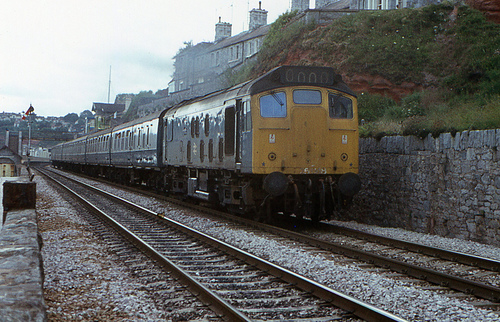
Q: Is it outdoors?
A: Yes, it is outdoors.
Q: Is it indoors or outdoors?
A: It is outdoors.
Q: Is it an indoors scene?
A: No, it is outdoors.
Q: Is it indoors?
A: No, it is outdoors.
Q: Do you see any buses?
A: No, there are no buses.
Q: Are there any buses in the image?
A: No, there are no buses.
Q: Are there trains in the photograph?
A: Yes, there is a train.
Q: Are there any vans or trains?
A: Yes, there is a train.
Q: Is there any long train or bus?
A: Yes, there is a long train.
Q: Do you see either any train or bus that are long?
A: Yes, the train is long.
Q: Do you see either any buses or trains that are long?
A: Yes, the train is long.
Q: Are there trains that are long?
A: Yes, there is a train that is long.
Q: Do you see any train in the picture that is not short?
A: Yes, there is a long train.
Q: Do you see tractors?
A: No, there are no tractors.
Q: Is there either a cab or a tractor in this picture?
A: No, there are no tractors or taxis.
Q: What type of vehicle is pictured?
A: The vehicle is a train.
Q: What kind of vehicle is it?
A: The vehicle is a train.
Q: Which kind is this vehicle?
A: That is a train.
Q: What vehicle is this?
A: That is a train.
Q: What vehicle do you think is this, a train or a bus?
A: That is a train.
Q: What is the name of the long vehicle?
A: The vehicle is a train.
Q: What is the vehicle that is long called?
A: The vehicle is a train.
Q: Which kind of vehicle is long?
A: The vehicle is a train.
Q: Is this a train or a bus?
A: This is a train.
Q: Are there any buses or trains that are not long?
A: No, there is a train but it is long.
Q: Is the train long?
A: Yes, the train is long.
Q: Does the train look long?
A: Yes, the train is long.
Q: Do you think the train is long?
A: Yes, the train is long.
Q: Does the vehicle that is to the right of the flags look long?
A: Yes, the train is long.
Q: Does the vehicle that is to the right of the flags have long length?
A: Yes, the train is long.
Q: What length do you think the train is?
A: The train is long.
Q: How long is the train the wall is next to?
A: The train is long.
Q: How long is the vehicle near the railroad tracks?
A: The train is long.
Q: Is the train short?
A: No, the train is long.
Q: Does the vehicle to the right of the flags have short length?
A: No, the train is long.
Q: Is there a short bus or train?
A: No, there is a train but it is long.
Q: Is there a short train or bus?
A: No, there is a train but it is long.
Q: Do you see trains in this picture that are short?
A: No, there is a train but it is long.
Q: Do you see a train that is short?
A: No, there is a train but it is long.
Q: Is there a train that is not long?
A: No, there is a train but it is long.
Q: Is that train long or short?
A: The train is long.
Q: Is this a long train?
A: Yes, this is a long train.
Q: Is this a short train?
A: No, this is a long train.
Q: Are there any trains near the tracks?
A: Yes, there is a train near the tracks.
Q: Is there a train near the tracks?
A: Yes, there is a train near the tracks.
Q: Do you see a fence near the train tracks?
A: No, there is a train near the train tracks.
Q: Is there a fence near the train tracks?
A: No, there is a train near the train tracks.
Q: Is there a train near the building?
A: Yes, there is a train near the building.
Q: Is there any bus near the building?
A: No, there is a train near the building.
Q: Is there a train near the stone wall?
A: Yes, there is a train near the wall.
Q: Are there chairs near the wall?
A: No, there is a train near the wall.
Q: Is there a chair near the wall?
A: No, there is a train near the wall.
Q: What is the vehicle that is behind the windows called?
A: The vehicle is a train.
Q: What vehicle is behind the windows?
A: The vehicle is a train.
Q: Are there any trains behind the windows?
A: Yes, there is a train behind the windows.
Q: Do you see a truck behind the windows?
A: No, there is a train behind the windows.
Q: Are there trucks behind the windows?
A: No, there is a train behind the windows.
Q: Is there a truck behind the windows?
A: No, there is a train behind the windows.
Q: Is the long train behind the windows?
A: Yes, the train is behind the windows.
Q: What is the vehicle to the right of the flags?
A: The vehicle is a train.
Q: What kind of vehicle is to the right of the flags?
A: The vehicle is a train.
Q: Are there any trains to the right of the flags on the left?
A: Yes, there is a train to the right of the flags.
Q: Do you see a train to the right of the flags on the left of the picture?
A: Yes, there is a train to the right of the flags.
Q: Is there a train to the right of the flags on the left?
A: Yes, there is a train to the right of the flags.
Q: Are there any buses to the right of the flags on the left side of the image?
A: No, there is a train to the right of the flags.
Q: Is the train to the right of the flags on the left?
A: Yes, the train is to the right of the flags.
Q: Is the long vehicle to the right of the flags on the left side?
A: Yes, the train is to the right of the flags.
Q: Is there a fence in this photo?
A: No, there are no fences.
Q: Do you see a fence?
A: No, there are no fences.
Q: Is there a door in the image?
A: Yes, there is a door.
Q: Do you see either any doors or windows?
A: Yes, there is a door.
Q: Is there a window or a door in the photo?
A: Yes, there is a door.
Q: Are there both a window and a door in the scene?
A: Yes, there are both a door and a window.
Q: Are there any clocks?
A: No, there are no clocks.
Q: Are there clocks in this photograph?
A: No, there are no clocks.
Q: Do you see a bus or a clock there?
A: No, there are no clocks or buses.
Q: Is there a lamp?
A: No, there are no lamps.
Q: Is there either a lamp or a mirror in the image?
A: No, there are no lamps or mirrors.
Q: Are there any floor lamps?
A: No, there are no floor lamps.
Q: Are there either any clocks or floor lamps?
A: No, there are no floor lamps or clocks.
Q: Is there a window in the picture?
A: Yes, there are windows.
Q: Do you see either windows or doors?
A: Yes, there are windows.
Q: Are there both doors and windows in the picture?
A: Yes, there are both windows and a door.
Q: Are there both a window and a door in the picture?
A: Yes, there are both a window and a door.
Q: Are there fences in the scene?
A: No, there are no fences.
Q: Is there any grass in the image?
A: Yes, there is grass.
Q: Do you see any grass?
A: Yes, there is grass.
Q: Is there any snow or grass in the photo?
A: Yes, there is grass.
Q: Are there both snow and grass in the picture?
A: No, there is grass but no snow.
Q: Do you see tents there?
A: No, there are no tents.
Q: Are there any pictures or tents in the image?
A: No, there are no tents or pictures.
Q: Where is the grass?
A: The grass is on the hill.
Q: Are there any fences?
A: No, there are no fences.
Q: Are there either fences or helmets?
A: No, there are no fences or helmets.